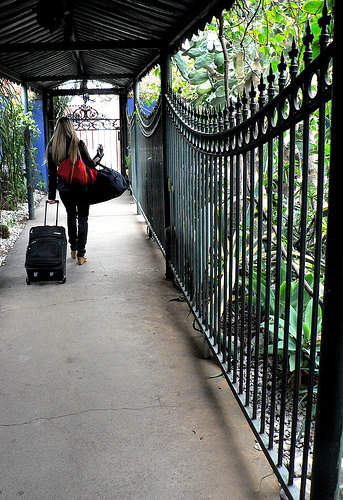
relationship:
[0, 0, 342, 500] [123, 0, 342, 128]
poles have decorative tops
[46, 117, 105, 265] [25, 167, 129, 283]
woman has luggage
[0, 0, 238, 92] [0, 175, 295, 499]
roof over cement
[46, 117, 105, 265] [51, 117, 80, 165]
woman has long hair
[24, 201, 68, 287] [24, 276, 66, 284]
luggage has wheels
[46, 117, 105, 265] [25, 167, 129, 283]
woman carrying luggage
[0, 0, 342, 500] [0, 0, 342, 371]
poles are in front of leaves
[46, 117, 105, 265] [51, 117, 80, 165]
woman has blonde hair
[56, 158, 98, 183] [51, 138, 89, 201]
bag on her back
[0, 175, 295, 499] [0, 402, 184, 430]
cement has a crack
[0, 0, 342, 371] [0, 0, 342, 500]
leaves overhang fence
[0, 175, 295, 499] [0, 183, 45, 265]
cement has stones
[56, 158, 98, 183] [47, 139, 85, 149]
bag on woman's shoulder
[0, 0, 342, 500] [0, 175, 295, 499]
poles are long a pathway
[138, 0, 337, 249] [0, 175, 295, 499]
tree lines a pathway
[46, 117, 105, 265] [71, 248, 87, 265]
woman wearing shoes